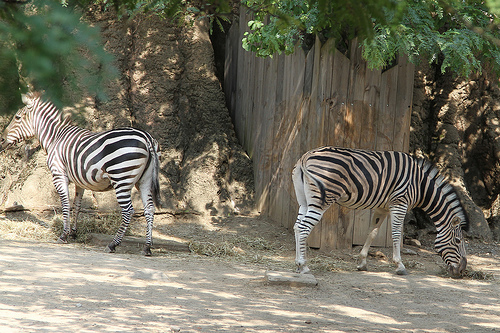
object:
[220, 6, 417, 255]
fence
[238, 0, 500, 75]
tree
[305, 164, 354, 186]
stripe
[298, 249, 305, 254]
stripe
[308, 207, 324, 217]
stripe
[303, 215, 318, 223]
stripe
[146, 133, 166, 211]
tail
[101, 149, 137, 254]
legs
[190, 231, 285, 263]
hay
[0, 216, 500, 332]
ground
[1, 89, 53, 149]
head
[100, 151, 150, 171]
stripe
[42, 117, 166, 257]
body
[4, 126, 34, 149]
zebra's jaw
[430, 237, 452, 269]
zebra's jaw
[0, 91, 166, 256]
zebra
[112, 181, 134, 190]
black stripe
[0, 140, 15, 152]
mouth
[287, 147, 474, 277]
zebra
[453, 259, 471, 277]
nose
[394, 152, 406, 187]
stripes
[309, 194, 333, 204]
stripes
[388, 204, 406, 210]
stripes